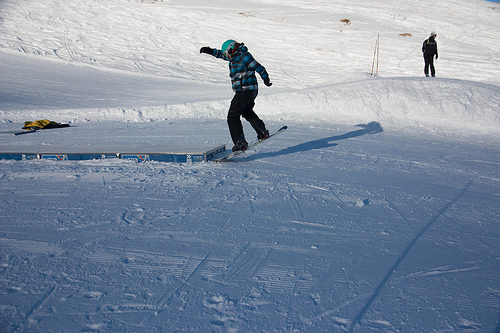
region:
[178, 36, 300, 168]
a person on a snowboard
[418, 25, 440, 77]
the person in black watches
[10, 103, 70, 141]
an abandon yellow coat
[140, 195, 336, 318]
the snow is a blueish white color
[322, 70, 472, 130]
this snow drift is good for skiing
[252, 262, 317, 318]
shoe prints in the snow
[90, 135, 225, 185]
a ramp to jump over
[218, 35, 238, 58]
this blue helmet is for safety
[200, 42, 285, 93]
this coat is blue purple and black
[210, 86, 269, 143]
black pants stand out in the snow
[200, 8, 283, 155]
person on snow board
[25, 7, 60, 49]
white clouds in blue sky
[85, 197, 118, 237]
white snow on hill side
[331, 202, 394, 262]
white snow on hill side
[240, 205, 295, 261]
white snow on hill side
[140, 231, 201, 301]
white snow on hill side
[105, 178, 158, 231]
white snow on hill side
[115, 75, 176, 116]
white snow on hill side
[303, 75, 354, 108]
white snow on hill side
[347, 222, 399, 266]
white snow on hill side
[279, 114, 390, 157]
shadow cast on the ground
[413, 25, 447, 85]
person stands on the snow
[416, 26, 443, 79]
person wears black cloths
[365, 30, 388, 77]
sticks on the snow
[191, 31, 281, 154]
person wears top squared coat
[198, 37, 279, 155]
person wears black pants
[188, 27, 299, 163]
person is on a snowboard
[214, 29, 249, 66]
a blue helmet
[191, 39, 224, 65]
a right arm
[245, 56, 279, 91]
a left arm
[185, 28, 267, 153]
person playing in snow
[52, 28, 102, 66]
white snow on hill side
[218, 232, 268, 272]
white snow on hill side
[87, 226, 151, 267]
white snow on hill side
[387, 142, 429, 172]
white snow on hill side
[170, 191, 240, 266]
white snow on hill side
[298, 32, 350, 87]
white snow on hill side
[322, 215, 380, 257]
white snow on hill side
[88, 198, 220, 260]
white snow on hill side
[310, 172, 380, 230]
white snow on hill side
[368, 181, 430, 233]
white snow on hill side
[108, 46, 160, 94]
white snow on hill side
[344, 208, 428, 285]
white snow on hill side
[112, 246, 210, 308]
white snow on hill side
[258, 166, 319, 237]
white snow on hill side